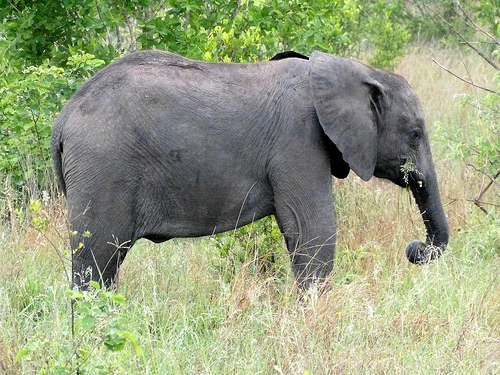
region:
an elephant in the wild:
[45, 39, 452, 299]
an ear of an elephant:
[309, 54, 384, 181]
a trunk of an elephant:
[405, 164, 452, 277]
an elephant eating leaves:
[313, 37, 455, 276]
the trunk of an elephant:
[408, 190, 453, 270]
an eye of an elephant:
[406, 120, 424, 144]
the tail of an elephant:
[46, 129, 75, 205]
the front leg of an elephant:
[263, 159, 342, 294]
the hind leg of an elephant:
[59, 177, 136, 304]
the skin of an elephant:
[184, 90, 264, 149]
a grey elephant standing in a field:
[21, 31, 459, 303]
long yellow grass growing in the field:
[212, 295, 361, 372]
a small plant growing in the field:
[16, 232, 125, 374]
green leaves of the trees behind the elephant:
[36, 5, 321, 63]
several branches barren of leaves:
[428, 18, 498, 223]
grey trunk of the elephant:
[381, 170, 459, 264]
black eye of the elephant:
[399, 118, 430, 153]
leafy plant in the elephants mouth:
[393, 155, 427, 195]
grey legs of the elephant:
[47, 206, 364, 313]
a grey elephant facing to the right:
[26, 52, 449, 314]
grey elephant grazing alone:
[13, 22, 459, 305]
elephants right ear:
[300, 55, 381, 185]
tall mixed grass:
[20, 206, 495, 366]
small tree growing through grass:
[17, 200, 102, 370]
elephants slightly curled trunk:
[400, 156, 466, 296]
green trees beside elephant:
[2, 0, 407, 60]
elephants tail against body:
[40, 111, 70, 221]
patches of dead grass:
[350, 196, 480, 276]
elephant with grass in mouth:
[390, 160, 435, 190]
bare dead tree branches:
[431, 16, 488, 79]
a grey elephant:
[31, 27, 471, 311]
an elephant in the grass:
[11, 25, 459, 341]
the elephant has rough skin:
[27, 48, 464, 309]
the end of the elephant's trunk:
[387, 214, 474, 276]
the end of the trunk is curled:
[403, 178, 468, 270]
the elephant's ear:
[279, 43, 388, 189]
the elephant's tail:
[45, 120, 67, 197]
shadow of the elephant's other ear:
[310, 125, 356, 188]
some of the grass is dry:
[5, 83, 496, 369]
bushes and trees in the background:
[2, 0, 345, 196]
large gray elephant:
[44, 44, 478, 302]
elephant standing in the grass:
[35, 37, 462, 334]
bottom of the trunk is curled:
[401, 233, 447, 268]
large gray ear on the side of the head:
[308, 47, 390, 189]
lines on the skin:
[249, 90, 286, 155]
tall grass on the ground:
[13, 195, 494, 372]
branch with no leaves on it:
[429, 61, 499, 101]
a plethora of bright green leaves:
[0, 2, 407, 222]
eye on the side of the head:
[407, 127, 420, 142]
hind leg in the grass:
[57, 211, 133, 329]